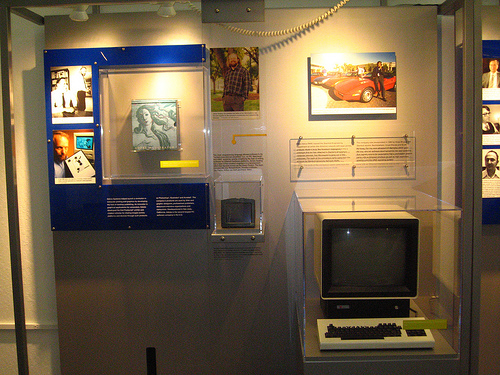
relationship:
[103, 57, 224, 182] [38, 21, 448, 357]
case on wall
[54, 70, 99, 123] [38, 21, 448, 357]
picture on wall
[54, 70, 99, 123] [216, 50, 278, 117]
picture of man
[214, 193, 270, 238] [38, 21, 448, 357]
plate on wall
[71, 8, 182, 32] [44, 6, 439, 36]
lights on ceiling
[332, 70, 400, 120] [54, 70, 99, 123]
car in picture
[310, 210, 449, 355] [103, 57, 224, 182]
computer in case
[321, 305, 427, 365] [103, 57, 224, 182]
keyboard in case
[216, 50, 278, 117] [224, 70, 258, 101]
man wearing shirt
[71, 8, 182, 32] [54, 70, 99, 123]
lights on picture